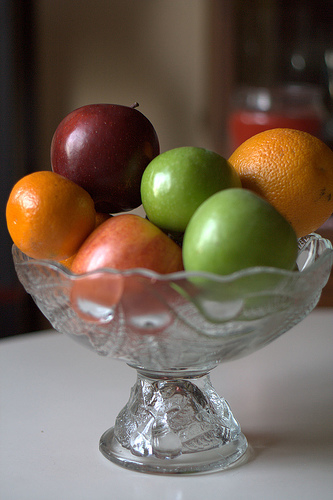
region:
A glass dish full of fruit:
[2, 89, 331, 478]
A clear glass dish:
[7, 234, 329, 479]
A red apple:
[34, 74, 164, 207]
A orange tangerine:
[2, 161, 104, 268]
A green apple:
[178, 182, 314, 285]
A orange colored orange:
[226, 110, 332, 248]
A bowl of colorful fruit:
[1, 65, 331, 385]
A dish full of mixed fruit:
[3, 68, 331, 405]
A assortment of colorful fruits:
[1, 74, 332, 334]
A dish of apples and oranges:
[1, 51, 331, 370]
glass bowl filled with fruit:
[9, 100, 327, 473]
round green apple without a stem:
[178, 185, 299, 292]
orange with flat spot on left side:
[4, 165, 95, 262]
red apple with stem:
[46, 93, 160, 212]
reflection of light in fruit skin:
[146, 164, 181, 203]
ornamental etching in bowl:
[120, 378, 222, 459]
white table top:
[10, 362, 261, 496]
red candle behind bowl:
[223, 78, 320, 157]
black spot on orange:
[314, 185, 332, 203]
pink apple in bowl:
[70, 210, 187, 327]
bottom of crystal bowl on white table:
[72, 345, 294, 492]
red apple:
[71, 211, 183, 322]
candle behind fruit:
[190, 65, 331, 235]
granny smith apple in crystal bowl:
[173, 190, 321, 313]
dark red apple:
[42, 97, 168, 208]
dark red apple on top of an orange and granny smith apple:
[14, 96, 196, 237]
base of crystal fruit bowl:
[87, 351, 264, 488]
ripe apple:
[164, 191, 307, 301]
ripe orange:
[5, 163, 102, 272]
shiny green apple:
[132, 147, 251, 238]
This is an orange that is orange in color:
[258, 129, 324, 231]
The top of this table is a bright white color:
[289, 394, 298, 427]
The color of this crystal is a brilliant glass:
[130, 401, 201, 488]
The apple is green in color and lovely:
[210, 187, 270, 287]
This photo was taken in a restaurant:
[81, 133, 311, 413]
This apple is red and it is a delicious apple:
[73, 107, 136, 207]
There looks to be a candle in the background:
[239, 78, 327, 146]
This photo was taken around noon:
[60, 132, 279, 462]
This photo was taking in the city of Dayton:
[54, 84, 284, 431]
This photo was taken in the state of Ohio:
[63, 117, 270, 450]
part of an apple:
[165, 179, 180, 203]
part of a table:
[233, 468, 248, 482]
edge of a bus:
[149, 456, 197, 492]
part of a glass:
[152, 430, 198, 469]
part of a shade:
[262, 424, 291, 471]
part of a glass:
[156, 393, 184, 429]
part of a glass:
[155, 412, 180, 443]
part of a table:
[110, 469, 131, 490]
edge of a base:
[165, 452, 208, 491]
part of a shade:
[250, 429, 280, 489]